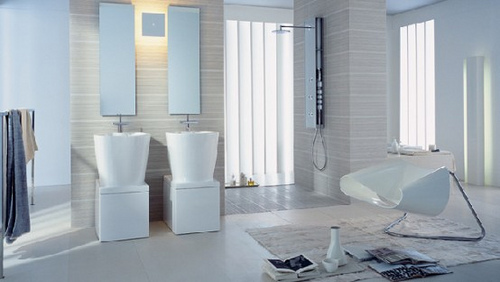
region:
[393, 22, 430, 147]
this is a window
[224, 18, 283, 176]
this is a door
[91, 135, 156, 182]
this is a sink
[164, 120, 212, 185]
this is a sink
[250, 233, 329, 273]
this is a book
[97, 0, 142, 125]
this is white in color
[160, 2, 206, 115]
this is white in color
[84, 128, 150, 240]
this is white in color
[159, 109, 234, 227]
this is white in color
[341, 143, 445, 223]
this is white in color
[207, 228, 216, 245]
part of a floor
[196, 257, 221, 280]
pat of a floor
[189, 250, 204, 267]
part of a f,loor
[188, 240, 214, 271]
part of a floor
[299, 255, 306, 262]
part of a paper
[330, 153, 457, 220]
modern chair all white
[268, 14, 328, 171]
modern shower next to window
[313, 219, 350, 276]
tea set white chimney tea cup with it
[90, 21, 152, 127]
mirror on stripped wall.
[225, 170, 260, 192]
soap and sham poo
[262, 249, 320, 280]
white book with black page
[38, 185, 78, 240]
light on floor and shadows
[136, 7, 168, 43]
light fixture with natural light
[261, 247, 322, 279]
Book on the ground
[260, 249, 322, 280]
Book on the floor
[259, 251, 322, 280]
Book is on the floor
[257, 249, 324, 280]
Book on the bathroom floor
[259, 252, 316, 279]
Book is on the bathroom floor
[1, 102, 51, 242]
Towels on a rack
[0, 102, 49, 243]
Towels are on a rack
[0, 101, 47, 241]
Towels on a towel rack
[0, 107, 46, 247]
Towels are on a towel rack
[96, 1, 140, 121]
white object on the wall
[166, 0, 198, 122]
white object on the wall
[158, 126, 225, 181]
large white plant pot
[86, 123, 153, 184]
large white plant pot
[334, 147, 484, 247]
modern white sitting chair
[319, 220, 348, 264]
white vase on the floor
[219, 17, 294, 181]
white curtains on the wall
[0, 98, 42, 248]
clothing rack full of cloths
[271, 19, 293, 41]
silver metal shower head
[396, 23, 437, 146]
white curtains on the window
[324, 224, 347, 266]
A white vase by a white cup.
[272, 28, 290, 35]
A round shower head.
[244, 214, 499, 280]
A white area rug.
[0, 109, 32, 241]
Long blue hanging towel.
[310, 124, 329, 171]
A hanging silver hose.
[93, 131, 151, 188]
Large round white sink that appears larger.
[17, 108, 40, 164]
A smaller hanging tan towel.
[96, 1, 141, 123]
mirror on the wall